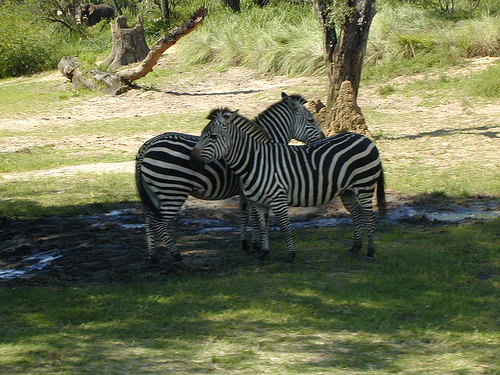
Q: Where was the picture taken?
A: It was taken at the field.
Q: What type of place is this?
A: It is a field.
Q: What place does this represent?
A: It represents the field.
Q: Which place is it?
A: It is a field.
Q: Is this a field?
A: Yes, it is a field.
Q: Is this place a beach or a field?
A: It is a field.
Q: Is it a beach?
A: No, it is a field.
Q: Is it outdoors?
A: Yes, it is outdoors.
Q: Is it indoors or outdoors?
A: It is outdoors.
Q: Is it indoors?
A: No, it is outdoors.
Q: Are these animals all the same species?
A: No, there are both zebras and elephants.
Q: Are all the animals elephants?
A: No, there are both zebras and elephants.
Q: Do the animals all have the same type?
A: No, there are both zebras and elephants.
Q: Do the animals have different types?
A: Yes, they are zebras and elephants.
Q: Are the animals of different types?
A: Yes, they are zebras and elephants.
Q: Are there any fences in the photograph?
A: No, there are no fences.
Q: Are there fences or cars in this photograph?
A: No, there are no fences or cars.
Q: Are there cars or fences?
A: No, there are no fences or cars.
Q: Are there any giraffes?
A: No, there are no giraffes.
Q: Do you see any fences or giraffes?
A: No, there are no giraffes or fences.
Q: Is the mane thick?
A: Yes, the mane is thick.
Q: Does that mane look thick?
A: Yes, the mane is thick.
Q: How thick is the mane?
A: The mane is thick.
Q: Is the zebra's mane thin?
A: No, the mane is thick.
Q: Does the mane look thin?
A: No, the mane is thick.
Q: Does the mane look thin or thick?
A: The mane is thick.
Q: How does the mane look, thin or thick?
A: The mane is thick.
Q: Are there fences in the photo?
A: No, there are no fences.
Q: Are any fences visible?
A: No, there are no fences.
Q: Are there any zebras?
A: Yes, there is a zebra.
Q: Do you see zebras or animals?
A: Yes, there is a zebra.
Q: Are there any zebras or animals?
A: Yes, there is a zebra.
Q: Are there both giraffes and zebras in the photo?
A: No, there is a zebra but no giraffes.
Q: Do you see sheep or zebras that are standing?
A: Yes, the zebra is standing.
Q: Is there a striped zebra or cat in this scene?
A: Yes, there is a striped zebra.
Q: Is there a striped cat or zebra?
A: Yes, there is a striped zebra.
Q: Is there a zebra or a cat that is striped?
A: Yes, the zebra is striped.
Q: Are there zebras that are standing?
A: Yes, there is a zebra that is standing.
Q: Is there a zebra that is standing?
A: Yes, there is a zebra that is standing.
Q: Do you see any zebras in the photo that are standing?
A: Yes, there is a zebra that is standing.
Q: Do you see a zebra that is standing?
A: Yes, there is a zebra that is standing.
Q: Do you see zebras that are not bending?
A: Yes, there is a zebra that is standing .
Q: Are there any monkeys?
A: No, there are no monkeys.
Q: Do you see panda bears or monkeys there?
A: No, there are no monkeys or panda bears.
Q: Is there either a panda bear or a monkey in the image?
A: No, there are no monkeys or panda bears.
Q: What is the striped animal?
A: The animal is a zebra.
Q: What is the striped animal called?
A: The animal is a zebra.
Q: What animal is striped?
A: The animal is a zebra.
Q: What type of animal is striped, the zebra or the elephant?
A: The zebra is striped.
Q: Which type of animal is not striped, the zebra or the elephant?
A: The elephant is not striped.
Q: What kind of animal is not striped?
A: The animal is an elephant.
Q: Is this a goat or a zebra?
A: This is a zebra.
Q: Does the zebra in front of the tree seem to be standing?
A: Yes, the zebra is standing.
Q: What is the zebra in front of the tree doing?
A: The zebra is standing.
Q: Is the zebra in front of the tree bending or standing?
A: The zebra is standing.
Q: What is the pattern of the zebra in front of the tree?
A: The zebra is striped.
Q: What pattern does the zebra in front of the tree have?
A: The zebra has striped pattern.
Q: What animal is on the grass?
A: The animal is a zebra.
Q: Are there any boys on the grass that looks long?
A: No, there is a zebra on the grass.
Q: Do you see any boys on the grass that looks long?
A: No, there is a zebra on the grass.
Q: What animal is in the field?
A: The zebra is in the field.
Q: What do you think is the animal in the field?
A: The animal is a zebra.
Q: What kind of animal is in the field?
A: The animal is a zebra.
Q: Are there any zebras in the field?
A: Yes, there is a zebra in the field.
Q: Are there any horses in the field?
A: No, there is a zebra in the field.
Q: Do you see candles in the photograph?
A: No, there are no candles.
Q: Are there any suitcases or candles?
A: No, there are no candles or suitcases.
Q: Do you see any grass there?
A: Yes, there is grass.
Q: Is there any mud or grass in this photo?
A: Yes, there is grass.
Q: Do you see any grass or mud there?
A: Yes, there is grass.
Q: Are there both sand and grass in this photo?
A: No, there is grass but no sand.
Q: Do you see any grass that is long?
A: Yes, there is long grass.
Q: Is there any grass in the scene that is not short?
A: Yes, there is long grass.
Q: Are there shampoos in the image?
A: No, there are no shampoos.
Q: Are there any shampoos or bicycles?
A: No, there are no shampoos or bicycles.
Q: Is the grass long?
A: Yes, the grass is long.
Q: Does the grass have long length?
A: Yes, the grass is long.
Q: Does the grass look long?
A: Yes, the grass is long.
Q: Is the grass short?
A: No, the grass is long.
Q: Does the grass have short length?
A: No, the grass is long.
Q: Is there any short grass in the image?
A: No, there is grass but it is long.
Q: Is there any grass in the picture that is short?
A: No, there is grass but it is long.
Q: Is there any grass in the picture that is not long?
A: No, there is grass but it is long.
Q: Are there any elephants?
A: Yes, there is an elephant.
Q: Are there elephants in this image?
A: Yes, there is an elephant.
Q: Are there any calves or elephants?
A: Yes, there is an elephant.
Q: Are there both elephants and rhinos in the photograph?
A: No, there is an elephant but no rhinos.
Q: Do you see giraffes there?
A: No, there are no giraffes.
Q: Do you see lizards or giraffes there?
A: No, there are no giraffes or lizards.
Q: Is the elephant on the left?
A: Yes, the elephant is on the left of the image.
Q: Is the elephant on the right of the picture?
A: No, the elephant is on the left of the image.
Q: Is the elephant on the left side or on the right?
A: The elephant is on the left of the image.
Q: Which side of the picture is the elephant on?
A: The elephant is on the left of the image.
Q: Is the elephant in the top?
A: Yes, the elephant is in the top of the image.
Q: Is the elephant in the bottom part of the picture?
A: No, the elephant is in the top of the image.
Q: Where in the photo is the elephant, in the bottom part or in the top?
A: The elephant is in the top of the image.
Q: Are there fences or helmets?
A: No, there are no fences or helmets.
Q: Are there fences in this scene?
A: No, there are no fences.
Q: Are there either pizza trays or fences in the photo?
A: No, there are no fences or pizza trays.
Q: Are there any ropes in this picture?
A: No, there are no ropes.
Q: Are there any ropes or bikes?
A: No, there are no ropes or bikes.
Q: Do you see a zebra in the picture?
A: Yes, there is a zebra.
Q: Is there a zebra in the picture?
A: Yes, there is a zebra.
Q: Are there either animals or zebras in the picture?
A: Yes, there is a zebra.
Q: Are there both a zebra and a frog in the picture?
A: No, there is a zebra but no frogs.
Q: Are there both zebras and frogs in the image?
A: No, there is a zebra but no frogs.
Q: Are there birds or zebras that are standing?
A: Yes, the zebra is standing.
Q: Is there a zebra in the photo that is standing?
A: Yes, there is a zebra that is standing.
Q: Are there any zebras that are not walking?
A: Yes, there is a zebra that is standing.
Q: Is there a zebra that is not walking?
A: Yes, there is a zebra that is standing.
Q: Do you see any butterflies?
A: No, there are no butterflies.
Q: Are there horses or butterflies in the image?
A: No, there are no butterflies or horses.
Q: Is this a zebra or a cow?
A: This is a zebra.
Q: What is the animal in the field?
A: The animal is a zebra.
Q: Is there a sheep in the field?
A: No, there is a zebra in the field.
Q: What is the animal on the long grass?
A: The animal is a zebra.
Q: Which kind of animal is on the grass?
A: The animal is a zebra.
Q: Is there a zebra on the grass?
A: Yes, there is a zebra on the grass.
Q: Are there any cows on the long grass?
A: No, there is a zebra on the grass.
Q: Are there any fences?
A: No, there are no fences.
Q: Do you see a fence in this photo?
A: No, there are no fences.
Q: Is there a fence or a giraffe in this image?
A: No, there are no fences or giraffes.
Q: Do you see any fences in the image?
A: No, there are no fences.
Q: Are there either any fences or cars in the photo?
A: No, there are no fences or cars.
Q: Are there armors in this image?
A: No, there are no armors.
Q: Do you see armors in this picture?
A: No, there are no armors.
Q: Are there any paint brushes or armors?
A: No, there are no armors or paint brushes.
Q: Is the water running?
A: Yes, the water is running.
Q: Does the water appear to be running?
A: Yes, the water is running.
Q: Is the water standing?
A: No, the water is running.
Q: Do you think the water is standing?
A: No, the water is running.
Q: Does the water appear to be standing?
A: No, the water is running.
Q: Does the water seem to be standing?
A: No, the water is running.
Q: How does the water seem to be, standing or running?
A: The water is running.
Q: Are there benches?
A: No, there are no benches.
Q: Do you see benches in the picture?
A: No, there are no benches.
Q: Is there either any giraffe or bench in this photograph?
A: No, there are no benches or giraffes.